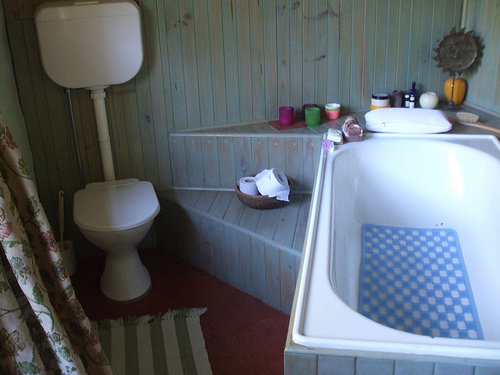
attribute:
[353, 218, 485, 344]
bath mat — white , blue 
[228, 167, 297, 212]
basket — wicker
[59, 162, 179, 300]
toilet — white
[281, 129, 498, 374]
large tub — large white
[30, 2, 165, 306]
toilet — white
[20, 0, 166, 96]
basin —  water 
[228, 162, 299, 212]
basket — wicker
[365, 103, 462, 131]
pillow — white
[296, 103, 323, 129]
cup — small, green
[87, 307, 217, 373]
rug — white, green 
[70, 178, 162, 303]
toilet bowl — white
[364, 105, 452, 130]
pillow — white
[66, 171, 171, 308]
toilet — white 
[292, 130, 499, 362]
tub — white bath, white, bath 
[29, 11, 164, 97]
basin — water 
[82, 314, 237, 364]
rug — green, white, striped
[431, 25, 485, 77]
decorative sub — metal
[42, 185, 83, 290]
toilet brush — white toilet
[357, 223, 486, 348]
mat — blue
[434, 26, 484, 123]
brush — back 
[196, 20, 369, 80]
wall — wood paneling wall